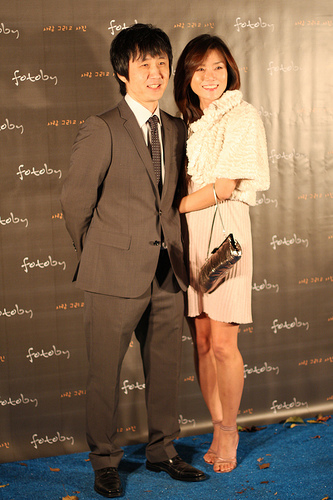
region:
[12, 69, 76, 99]
white words on wall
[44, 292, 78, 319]
gold words in the background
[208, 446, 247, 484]
clear shoes on woman's feet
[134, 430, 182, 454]
wrinkles in man's pants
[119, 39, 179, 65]
black bangs on man's head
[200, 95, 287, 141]
white collar on jacket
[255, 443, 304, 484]
small leaves on floor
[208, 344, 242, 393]
muscles in woman's knees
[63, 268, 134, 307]
edge of brown jacket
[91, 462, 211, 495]
man's shiny black shoes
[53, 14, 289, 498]
Couple posing for picture.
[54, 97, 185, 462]
Man dressed in brown suit.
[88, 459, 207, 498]
Man wearing black leather shoes.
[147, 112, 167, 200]
Man wearing brown tie with small white dots around neck.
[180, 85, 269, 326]
Woman wearing beige pleated dress.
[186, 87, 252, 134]
Gathers around top of dress.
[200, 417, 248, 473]
Woman wearing beige high hell sandals.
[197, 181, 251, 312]
Woman has silver purse hanging on arm.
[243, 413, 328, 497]
Blue carpet with leaves.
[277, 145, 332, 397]
Brown background with white and gold writing.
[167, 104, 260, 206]
short cream colored cape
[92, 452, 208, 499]
shiny black shoes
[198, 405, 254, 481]
ankle strapped high heels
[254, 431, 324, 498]
an outdoor blue carpet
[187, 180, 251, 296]
a metallic like handbag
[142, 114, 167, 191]
brown dotted neck tie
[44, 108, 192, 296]
Single breasted brown suit coat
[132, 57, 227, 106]
two bright smiles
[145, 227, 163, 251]
a suit coat button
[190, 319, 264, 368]
a woman's knees show beneath her short skirt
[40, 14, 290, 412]
man and woman standing together.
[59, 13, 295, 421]
man and woman posing together.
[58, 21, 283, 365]
man and woman smiling together.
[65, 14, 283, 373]
man and woman together.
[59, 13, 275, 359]
man and woman together well dressed.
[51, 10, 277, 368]
attractive couple standing together.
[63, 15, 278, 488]
beautiful couple standing together.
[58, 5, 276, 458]
attractive couple posing together.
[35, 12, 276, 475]
beautiful couple posing together.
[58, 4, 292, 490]
well dressed couple together for pictures.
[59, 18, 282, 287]
asian man and woman posing for pictures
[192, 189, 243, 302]
silver purse hanging from women's arm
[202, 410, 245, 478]
brown sandals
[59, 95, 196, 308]
grey suit jacket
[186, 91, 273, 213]
white shawl on shoulders of woman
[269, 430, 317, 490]
blue carpet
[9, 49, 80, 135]
dark wall with white and red words on it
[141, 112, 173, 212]
grey tie with white spots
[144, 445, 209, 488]
black loafer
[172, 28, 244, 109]
smiling face of a asian woman with brown hair